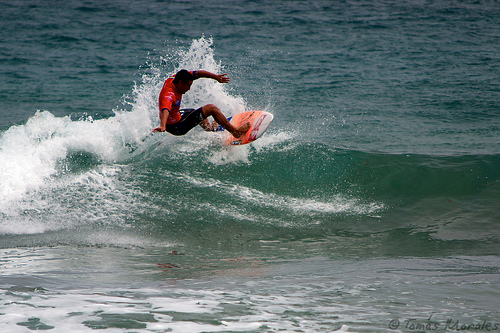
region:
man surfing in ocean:
[106, 39, 285, 175]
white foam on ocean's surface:
[40, 288, 238, 326]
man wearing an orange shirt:
[133, 49, 289, 151]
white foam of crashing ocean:
[10, 33, 270, 194]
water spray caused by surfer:
[125, 31, 240, 119]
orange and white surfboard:
[202, 98, 298, 156]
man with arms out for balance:
[134, 55, 274, 171]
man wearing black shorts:
[155, 96, 220, 158]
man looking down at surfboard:
[133, 47, 311, 167]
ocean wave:
[94, 127, 490, 231]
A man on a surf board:
[150, 60, 285, 165]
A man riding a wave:
[141, 55, 286, 170]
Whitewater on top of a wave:
[0, 47, 155, 187]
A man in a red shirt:
[153, 58, 200, 131]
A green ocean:
[281, 9, 493, 206]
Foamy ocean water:
[6, 257, 359, 327]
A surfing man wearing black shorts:
[153, 62, 227, 146]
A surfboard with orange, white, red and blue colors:
[201, 102, 291, 156]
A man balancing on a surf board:
[118, 53, 304, 168]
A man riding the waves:
[141, 45, 323, 266]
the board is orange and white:
[215, 105, 336, 167]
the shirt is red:
[147, 79, 192, 130]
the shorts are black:
[174, 109, 211, 139]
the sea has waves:
[17, 55, 472, 255]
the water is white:
[37, 124, 124, 152]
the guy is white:
[141, 62, 284, 162]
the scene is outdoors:
[5, 5, 497, 325]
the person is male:
[140, 45, 306, 155]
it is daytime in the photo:
[5, 15, 499, 329]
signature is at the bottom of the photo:
[382, 309, 499, 332]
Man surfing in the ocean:
[136, 52, 282, 153]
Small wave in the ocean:
[15, 110, 499, 212]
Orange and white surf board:
[214, 103, 276, 150]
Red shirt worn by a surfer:
[154, 62, 192, 129]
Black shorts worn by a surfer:
[167, 106, 204, 134]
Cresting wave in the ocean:
[7, 124, 497, 211]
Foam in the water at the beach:
[12, 283, 285, 331]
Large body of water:
[4, 2, 493, 69]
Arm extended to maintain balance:
[192, 63, 235, 85]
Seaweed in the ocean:
[152, 259, 179, 275]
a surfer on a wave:
[150, 68, 274, 145]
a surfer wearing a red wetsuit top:
[157, 69, 192, 125]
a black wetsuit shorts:
[167, 111, 203, 139]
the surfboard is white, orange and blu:
[211, 110, 273, 146]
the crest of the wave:
[299, 137, 499, 168]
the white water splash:
[0, 83, 152, 201]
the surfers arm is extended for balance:
[191, 68, 231, 85]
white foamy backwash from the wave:
[0, 277, 369, 331]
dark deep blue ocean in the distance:
[270, 0, 496, 115]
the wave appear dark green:
[256, 147, 496, 197]